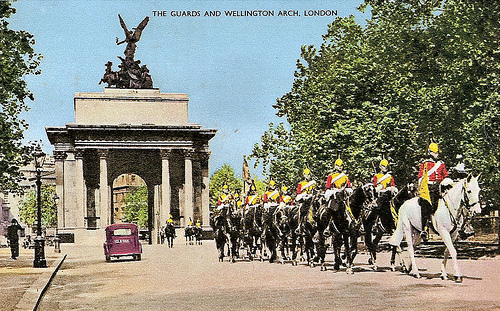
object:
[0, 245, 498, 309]
ground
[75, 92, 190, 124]
wall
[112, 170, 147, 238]
door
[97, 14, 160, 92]
statue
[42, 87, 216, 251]
stone structue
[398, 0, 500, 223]
trees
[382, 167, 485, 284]
horse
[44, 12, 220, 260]
building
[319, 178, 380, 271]
black horse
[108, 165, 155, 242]
arch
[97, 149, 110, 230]
column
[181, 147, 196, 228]
pillar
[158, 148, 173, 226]
pillar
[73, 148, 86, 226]
pillar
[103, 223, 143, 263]
car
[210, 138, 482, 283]
military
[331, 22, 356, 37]
leaves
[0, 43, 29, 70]
leaves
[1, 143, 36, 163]
leaves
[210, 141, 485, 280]
pack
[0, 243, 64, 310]
sidewalk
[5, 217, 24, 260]
man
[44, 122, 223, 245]
doorway